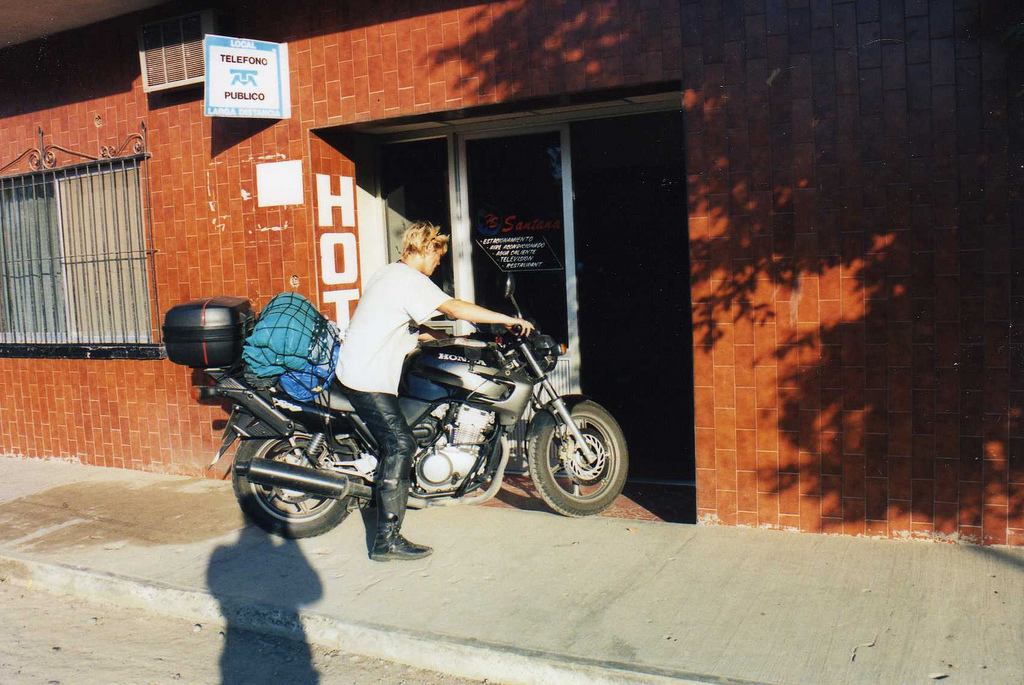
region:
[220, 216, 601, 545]
Girl sitting on a motorcycle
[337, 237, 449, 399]
White short sleeved tee shirt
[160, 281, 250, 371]
A black luggage rack on motorcycle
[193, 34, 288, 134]
White and blue sign next to door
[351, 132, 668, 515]
Motorcycle going through glass doorway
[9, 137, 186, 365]
Decorative metal bars on window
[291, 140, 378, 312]
Large white letters spell the word HOT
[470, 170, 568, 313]
Red and white lettering on glass door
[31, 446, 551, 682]
Sidewalk next to building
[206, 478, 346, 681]
shadow of a person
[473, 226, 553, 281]
white writing on the window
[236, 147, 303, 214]
white sign on the side of the building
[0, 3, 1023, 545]
building is made of brick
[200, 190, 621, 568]
woman is next to a motorcycle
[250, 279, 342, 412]
blue and black sack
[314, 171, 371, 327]
white letters on the side of the building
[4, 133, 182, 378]
window on the side of the building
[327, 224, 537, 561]
a young man on a motorcycle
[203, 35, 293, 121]
a public telephone sign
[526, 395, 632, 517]
front wheel of a motorcycle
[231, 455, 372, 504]
muffler on a motorcycle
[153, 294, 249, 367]
motorcycle storage compartment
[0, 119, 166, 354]
a window with bars on the outside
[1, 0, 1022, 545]
a red brick building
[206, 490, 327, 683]
the shadow of the photographer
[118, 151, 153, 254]
pane on the window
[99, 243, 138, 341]
pane on the window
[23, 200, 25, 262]
pane on the window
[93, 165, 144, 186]
pane on the window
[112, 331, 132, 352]
pane on the window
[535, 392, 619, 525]
wheel of the bike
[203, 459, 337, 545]
wheel of the bike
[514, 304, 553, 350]
hand of the person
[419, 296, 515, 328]
arm of the person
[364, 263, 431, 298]
shoulder of the person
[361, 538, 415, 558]
foot of the person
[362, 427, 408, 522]
leg of the person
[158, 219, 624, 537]
motorcycle in front of brick building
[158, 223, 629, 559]
person in front of brick building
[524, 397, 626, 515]
front wheel of motorcycle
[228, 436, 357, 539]
rear wheel of motorcycle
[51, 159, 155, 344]
window in front of brick building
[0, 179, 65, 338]
window in front of brick building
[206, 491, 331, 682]
shadow of person on sidewalk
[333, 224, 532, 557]
person wearing leather pants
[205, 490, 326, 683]
shadow of person taking a picture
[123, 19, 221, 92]
a light color air conditioner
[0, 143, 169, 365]
a window with wrought iron bars over it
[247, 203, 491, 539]
Person in white shirt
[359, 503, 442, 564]
Black boot on person's foot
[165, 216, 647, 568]
a person n a motorcycle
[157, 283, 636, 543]
a motorcycle in front of a door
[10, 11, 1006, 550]
a red brick building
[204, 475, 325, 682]
a reflection of a person on the sidewalk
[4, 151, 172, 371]
window on the brick building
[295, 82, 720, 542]
door way of the brick building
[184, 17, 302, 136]
a sign on the brick building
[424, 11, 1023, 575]
reflection of a tree on the brick building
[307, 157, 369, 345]
letters on the brick building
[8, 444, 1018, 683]
sidewalk in front of the brick building